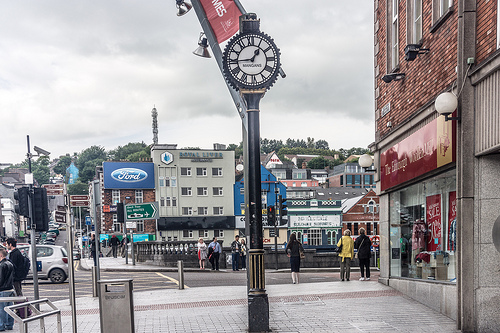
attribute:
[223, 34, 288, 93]
clock — white, round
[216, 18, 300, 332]
pole — black, standing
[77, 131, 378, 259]
buildings — big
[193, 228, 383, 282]
people — walking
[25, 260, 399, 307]
street — grey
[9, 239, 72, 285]
car — small, grey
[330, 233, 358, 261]
jacket — yellow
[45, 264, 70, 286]
wheel — rear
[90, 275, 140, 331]
trash — silver